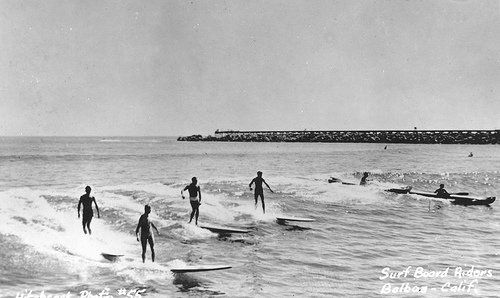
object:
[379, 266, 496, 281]
text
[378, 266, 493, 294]
sign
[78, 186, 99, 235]
people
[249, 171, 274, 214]
people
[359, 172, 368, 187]
people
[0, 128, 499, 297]
ocean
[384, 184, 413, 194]
surfboard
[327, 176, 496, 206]
boat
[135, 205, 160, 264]
person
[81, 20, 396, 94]
skies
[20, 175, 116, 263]
arrow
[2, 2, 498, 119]
sky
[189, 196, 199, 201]
white shorts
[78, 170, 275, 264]
surfers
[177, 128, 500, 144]
bridge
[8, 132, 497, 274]
water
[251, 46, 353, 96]
white clouds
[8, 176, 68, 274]
nose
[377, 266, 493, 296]
photographer credit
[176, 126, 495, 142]
rocks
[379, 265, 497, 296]
white text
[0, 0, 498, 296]
photo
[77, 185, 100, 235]
person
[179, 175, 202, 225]
person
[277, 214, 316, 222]
surfboard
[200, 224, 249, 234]
surf board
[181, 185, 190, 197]
right arm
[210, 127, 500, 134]
railing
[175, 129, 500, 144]
promontory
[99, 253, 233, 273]
surfboard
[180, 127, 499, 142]
wharf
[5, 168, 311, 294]
waves